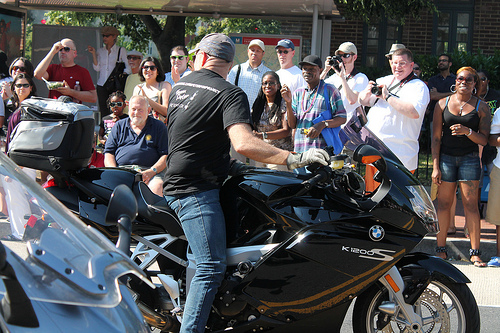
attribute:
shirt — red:
[46, 63, 95, 95]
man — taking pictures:
[318, 39, 369, 120]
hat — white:
[331, 40, 358, 57]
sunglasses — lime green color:
[167, 52, 189, 62]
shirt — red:
[49, 63, 86, 102]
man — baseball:
[155, 29, 322, 319]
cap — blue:
[183, 37, 238, 59]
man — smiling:
[363, 47, 430, 174]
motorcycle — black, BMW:
[43, 122, 477, 328]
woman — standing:
[10, 55, 32, 79]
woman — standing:
[4, 75, 36, 115]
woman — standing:
[132, 57, 170, 115]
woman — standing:
[252, 72, 286, 147]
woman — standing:
[430, 67, 487, 267]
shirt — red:
[24, 27, 96, 117]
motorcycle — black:
[112, 159, 468, 317]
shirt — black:
[164, 68, 252, 195]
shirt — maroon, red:
[47, 61, 95, 101]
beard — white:
[129, 115, 144, 127]